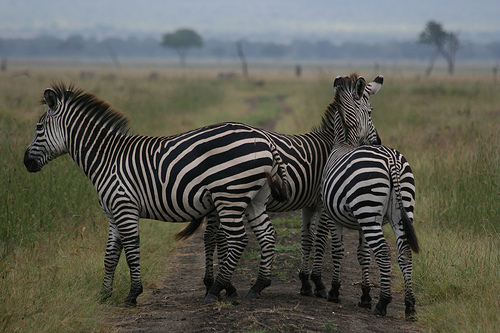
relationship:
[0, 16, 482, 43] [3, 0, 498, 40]
clouds in sky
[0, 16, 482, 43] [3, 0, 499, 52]
clouds in sky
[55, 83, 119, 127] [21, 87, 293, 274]
mane on zebra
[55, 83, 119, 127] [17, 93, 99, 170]
mane on head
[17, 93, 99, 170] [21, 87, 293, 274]
head of zebra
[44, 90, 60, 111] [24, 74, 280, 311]
ear of zebra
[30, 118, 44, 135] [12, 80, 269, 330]
eye of zebra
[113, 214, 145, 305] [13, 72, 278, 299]
leg of zebra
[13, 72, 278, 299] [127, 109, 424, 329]
zebra walking on path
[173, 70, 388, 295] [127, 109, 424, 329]
zebra walking on path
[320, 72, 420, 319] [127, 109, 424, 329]
zebra walking on path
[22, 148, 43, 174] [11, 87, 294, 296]
nose on zebra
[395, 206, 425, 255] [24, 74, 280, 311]
tail on zebra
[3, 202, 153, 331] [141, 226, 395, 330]
grass surrounding dirt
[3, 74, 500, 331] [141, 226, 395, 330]
grass surrounding dirt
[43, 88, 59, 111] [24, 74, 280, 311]
ear on zebra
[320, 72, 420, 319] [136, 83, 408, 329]
zebra on path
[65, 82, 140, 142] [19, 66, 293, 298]
short hairs on zebra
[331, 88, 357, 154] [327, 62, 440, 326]
short hairs on zebra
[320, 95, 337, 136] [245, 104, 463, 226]
short hairs on zebra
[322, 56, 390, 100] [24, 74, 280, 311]
ears on zebra